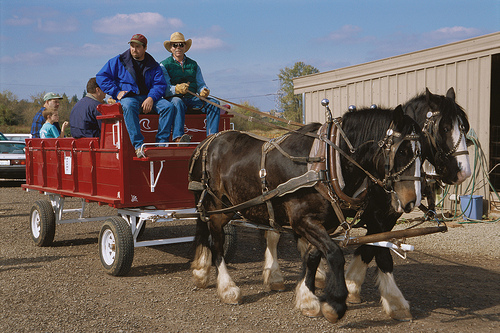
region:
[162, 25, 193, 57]
head of a person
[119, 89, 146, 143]
leg of a person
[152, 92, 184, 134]
leg of a person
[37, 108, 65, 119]
head of a person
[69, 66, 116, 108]
head of a person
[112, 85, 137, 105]
hand of a person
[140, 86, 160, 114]
hand of a person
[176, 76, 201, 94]
hand of a person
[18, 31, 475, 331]
Two brown horses pulling a red riding cart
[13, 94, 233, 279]
A red riding cart being pulled by horses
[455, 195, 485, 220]
A blue plastic trash can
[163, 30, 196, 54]
A straw hat being worn by the driver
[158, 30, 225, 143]
The driver on the cart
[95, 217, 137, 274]
The front wheel of the cart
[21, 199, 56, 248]
The back wheel of the cart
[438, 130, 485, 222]
A green garden hose hanging on a building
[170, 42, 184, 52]
The sunglasses of the driver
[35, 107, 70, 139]
A boy in the back of the horse drawn cart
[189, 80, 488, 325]
two horses walking on the street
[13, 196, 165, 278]
wheels of the wagon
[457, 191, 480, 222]
blue bucket next to a building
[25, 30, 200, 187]
people in the wagon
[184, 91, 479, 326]
two large brown horses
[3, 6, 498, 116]
bright blue sky with few clouds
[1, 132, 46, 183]
cars in the parking lot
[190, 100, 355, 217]
leather straps on a horse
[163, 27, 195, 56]
straw cowboy hat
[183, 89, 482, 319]
two horses pulling a wagon of people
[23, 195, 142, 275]
two wheels on the wagon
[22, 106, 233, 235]
a red wagon on the ground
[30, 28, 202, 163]
people sitting inside the red wagon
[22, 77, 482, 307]
two brown horses strapped to a red wagon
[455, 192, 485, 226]
blue bucket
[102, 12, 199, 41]
a white cloud in the blue sky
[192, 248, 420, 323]
white and black horse hooves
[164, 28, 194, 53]
a cowboy hat on a man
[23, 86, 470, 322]
Two horses pulling a red wagon.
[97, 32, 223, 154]
Two men sitting in front of the wagon.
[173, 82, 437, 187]
A man holding the horse reins.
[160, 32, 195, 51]
A cowboy hat on the man's head.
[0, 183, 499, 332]
The ground is dirt.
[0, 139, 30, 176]
A white car behind the wagon.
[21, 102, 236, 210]
A bright red wagon.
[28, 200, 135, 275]
Black rubber tires on the wagon.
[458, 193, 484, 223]
A blue bucket on the ground.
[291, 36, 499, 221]
A brown building next to the horses.